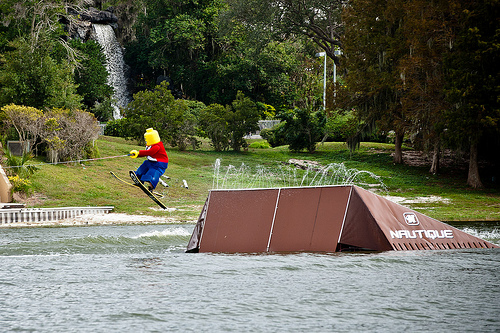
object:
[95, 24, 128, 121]
waterfall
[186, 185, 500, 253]
ramp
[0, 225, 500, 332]
water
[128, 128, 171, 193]
skier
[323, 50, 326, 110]
posts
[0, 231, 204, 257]
wake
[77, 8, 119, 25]
rock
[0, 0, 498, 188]
trees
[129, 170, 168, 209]
skis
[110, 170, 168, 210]
skis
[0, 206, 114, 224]
wall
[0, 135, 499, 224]
shore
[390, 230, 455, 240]
word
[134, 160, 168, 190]
pants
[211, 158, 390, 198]
spray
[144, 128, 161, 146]
bucket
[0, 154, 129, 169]
rope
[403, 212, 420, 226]
logo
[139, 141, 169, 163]
shirt